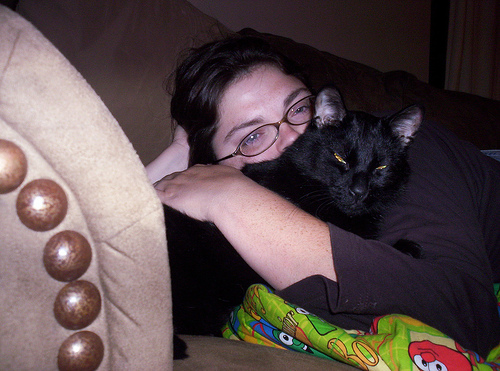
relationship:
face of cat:
[322, 123, 405, 218] [160, 85, 423, 358]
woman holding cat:
[148, 36, 500, 362] [160, 85, 423, 358]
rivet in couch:
[0, 139, 27, 194] [0, 2, 216, 369]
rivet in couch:
[16, 178, 68, 234] [0, 2, 216, 369]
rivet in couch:
[45, 229, 93, 283] [0, 2, 216, 369]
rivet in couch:
[51, 277, 100, 332] [0, 2, 216, 369]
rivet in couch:
[53, 331, 104, 371] [0, 2, 216, 369]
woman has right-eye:
[148, 36, 500, 362] [241, 131, 269, 147]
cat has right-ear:
[160, 85, 423, 358] [310, 83, 347, 132]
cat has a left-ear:
[160, 85, 423, 358] [385, 104, 423, 148]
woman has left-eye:
[148, 36, 500, 362] [292, 104, 311, 115]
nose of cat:
[351, 188, 366, 201] [160, 85, 423, 358]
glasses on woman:
[215, 94, 321, 165] [148, 36, 500, 362]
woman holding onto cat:
[148, 36, 500, 362] [160, 85, 423, 358]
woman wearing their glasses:
[148, 36, 500, 362] [215, 94, 321, 165]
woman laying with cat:
[148, 36, 500, 362] [160, 85, 423, 358]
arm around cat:
[150, 112, 499, 358] [160, 85, 423, 358]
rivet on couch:
[0, 139, 27, 194] [0, 2, 216, 369]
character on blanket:
[408, 339, 476, 370] [223, 281, 499, 370]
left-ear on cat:
[385, 104, 423, 148] [160, 85, 423, 358]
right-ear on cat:
[310, 83, 347, 132] [160, 85, 423, 358]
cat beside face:
[160, 85, 423, 358] [215, 74, 317, 169]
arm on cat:
[150, 112, 499, 358] [160, 85, 423, 358]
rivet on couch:
[53, 331, 104, 371] [0, 2, 216, 369]